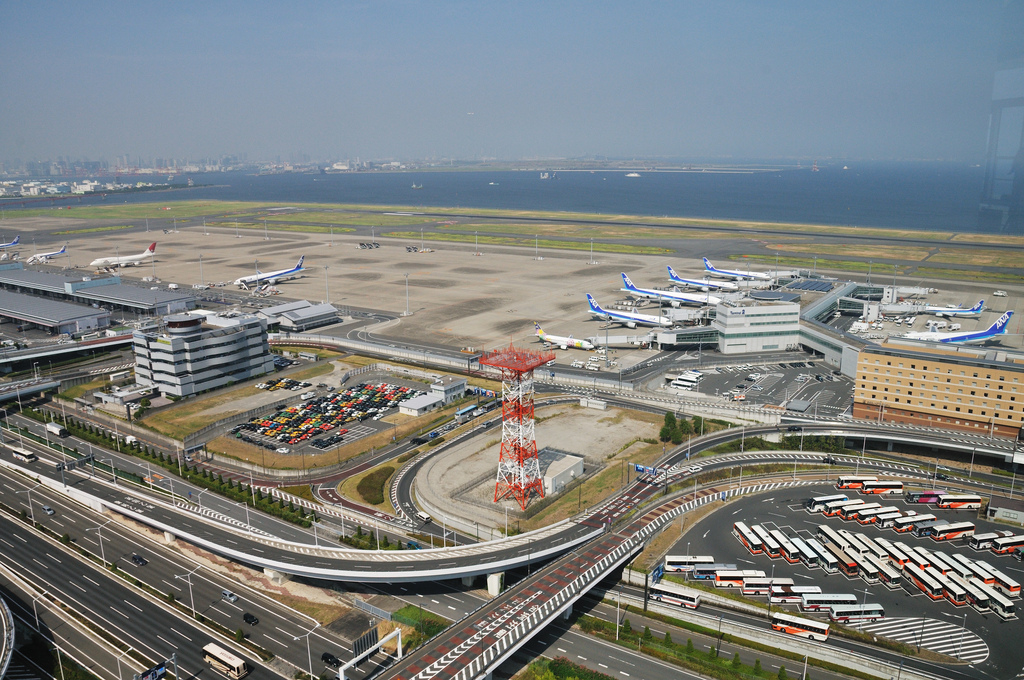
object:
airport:
[5, 199, 991, 671]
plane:
[699, 255, 772, 283]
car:
[336, 428, 350, 436]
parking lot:
[228, 366, 430, 457]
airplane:
[89, 241, 157, 269]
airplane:
[232, 253, 310, 290]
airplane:
[584, 292, 675, 329]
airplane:
[617, 271, 719, 308]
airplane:
[664, 264, 738, 291]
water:
[32, 163, 995, 237]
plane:
[892, 310, 1016, 345]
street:
[364, 478, 840, 677]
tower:
[473, 342, 558, 513]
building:
[128, 308, 277, 401]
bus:
[730, 521, 765, 555]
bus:
[751, 524, 781, 560]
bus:
[789, 537, 823, 572]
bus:
[803, 538, 838, 572]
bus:
[923, 566, 967, 607]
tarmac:
[11, 221, 789, 373]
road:
[2, 515, 289, 676]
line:
[154, 631, 181, 649]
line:
[169, 625, 192, 641]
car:
[241, 612, 259, 626]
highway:
[3, 471, 387, 677]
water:
[3, 160, 992, 234]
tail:
[145, 237, 159, 251]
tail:
[580, 290, 602, 316]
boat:
[621, 169, 643, 178]